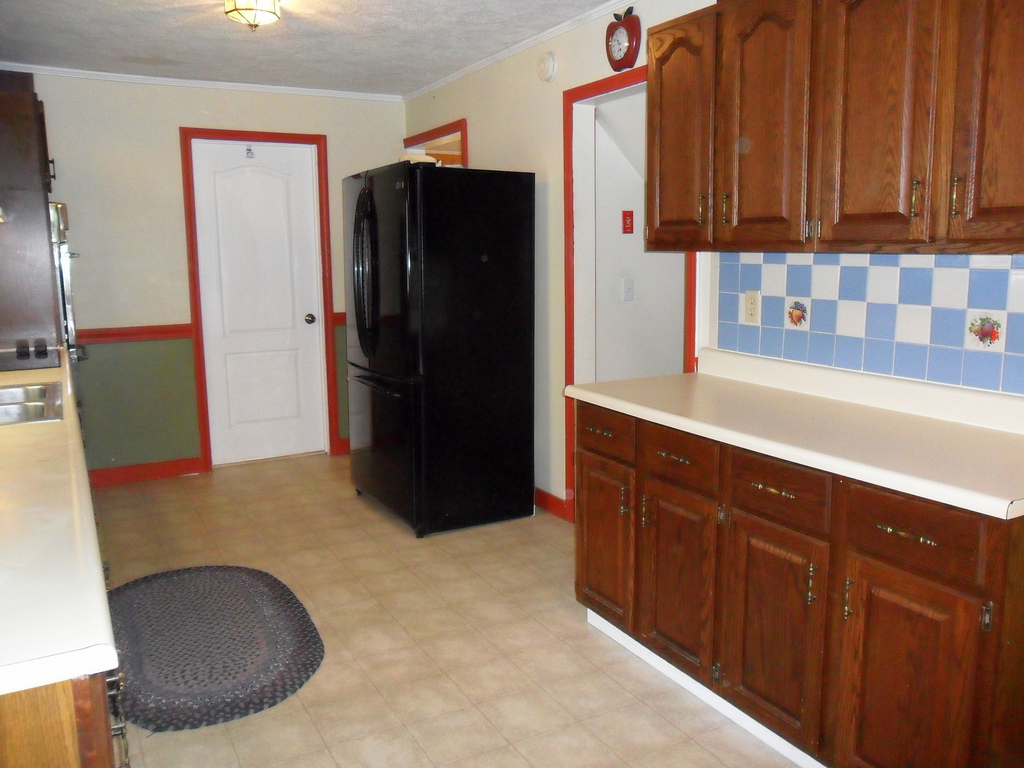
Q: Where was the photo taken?
A: In the empty kitchen.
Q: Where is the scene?
A: In the empty kitchen.